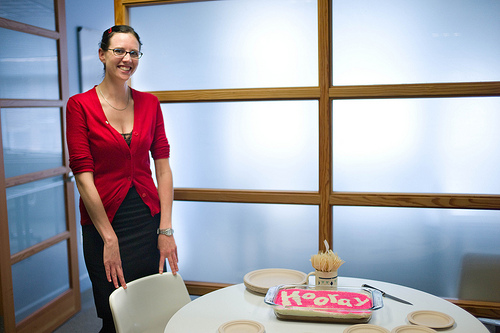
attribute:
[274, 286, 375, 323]
cake — homemade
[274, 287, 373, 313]
frosting — pink, white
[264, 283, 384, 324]
pan — glass, blue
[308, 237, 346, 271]
forks — plastic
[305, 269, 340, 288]
mug — coffee mug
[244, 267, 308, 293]
plates — large, paper, stacked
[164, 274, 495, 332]
table — round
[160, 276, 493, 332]
tablecloth — white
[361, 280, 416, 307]
knife — metal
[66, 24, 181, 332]
woman — smiling, young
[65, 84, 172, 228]
cardigan — red, button-down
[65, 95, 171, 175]
sleeves — rolled up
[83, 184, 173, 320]
dress — black, knee length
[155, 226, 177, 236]
watch — ladies watch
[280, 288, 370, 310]
word — hooray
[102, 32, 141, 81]
face — smiling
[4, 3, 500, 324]
panel — glass, frosted